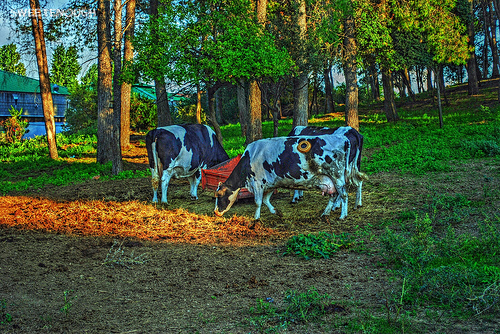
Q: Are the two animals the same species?
A: Yes, all the animals are cows.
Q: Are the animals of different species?
A: No, all the animals are cows.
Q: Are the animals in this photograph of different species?
A: No, all the animals are cows.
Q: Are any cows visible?
A: Yes, there is a cow.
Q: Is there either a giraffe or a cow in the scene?
A: Yes, there is a cow.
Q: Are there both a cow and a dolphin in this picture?
A: No, there is a cow but no dolphins.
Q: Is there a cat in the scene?
A: No, there are no cats.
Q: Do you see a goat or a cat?
A: No, there are no cats or goats.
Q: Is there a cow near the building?
A: Yes, there is a cow near the building.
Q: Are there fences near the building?
A: No, there is a cow near the building.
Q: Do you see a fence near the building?
A: No, there is a cow near the building.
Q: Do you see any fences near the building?
A: No, there is a cow near the building.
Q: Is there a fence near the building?
A: No, there is a cow near the building.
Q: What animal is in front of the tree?
A: The cow is in front of the tree.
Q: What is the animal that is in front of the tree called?
A: The animal is a cow.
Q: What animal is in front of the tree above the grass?
A: The animal is a cow.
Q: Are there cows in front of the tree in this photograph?
A: Yes, there is a cow in front of the tree.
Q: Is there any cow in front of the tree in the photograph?
A: Yes, there is a cow in front of the tree.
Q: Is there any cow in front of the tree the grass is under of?
A: Yes, there is a cow in front of the tree.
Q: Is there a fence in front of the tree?
A: No, there is a cow in front of the tree.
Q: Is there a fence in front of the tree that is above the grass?
A: No, there is a cow in front of the tree.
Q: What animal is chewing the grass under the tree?
A: The cow is chewing the grass.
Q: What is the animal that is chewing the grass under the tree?
A: The animal is a cow.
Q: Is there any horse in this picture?
A: No, there are no horses.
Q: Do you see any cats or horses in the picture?
A: No, there are no horses or cats.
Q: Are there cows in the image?
A: Yes, there is a cow.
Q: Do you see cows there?
A: Yes, there is a cow.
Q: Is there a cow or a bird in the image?
A: Yes, there is a cow.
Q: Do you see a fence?
A: No, there are no fences.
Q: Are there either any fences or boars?
A: No, there are no fences or boars.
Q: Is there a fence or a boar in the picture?
A: No, there are no fences or boars.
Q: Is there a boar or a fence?
A: No, there are no fences or boars.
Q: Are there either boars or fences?
A: No, there are no fences or boars.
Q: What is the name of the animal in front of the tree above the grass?
A: The animal is a cow.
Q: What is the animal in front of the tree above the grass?
A: The animal is a cow.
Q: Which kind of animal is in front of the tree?
A: The animal is a cow.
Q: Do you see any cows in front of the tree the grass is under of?
A: Yes, there is a cow in front of the tree.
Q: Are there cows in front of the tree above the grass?
A: Yes, there is a cow in front of the tree.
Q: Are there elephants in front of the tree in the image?
A: No, there is a cow in front of the tree.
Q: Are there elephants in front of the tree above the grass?
A: No, there is a cow in front of the tree.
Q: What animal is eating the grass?
A: The cow is eating the grass.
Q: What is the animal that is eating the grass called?
A: The animal is a cow.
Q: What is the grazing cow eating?
A: The cow is eating grass.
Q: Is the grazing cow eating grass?
A: Yes, the cow is eating grass.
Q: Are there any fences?
A: No, there are no fences.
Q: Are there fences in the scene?
A: No, there are no fences.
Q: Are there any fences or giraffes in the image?
A: No, there are no fences or giraffes.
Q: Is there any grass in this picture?
A: Yes, there is grass.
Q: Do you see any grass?
A: Yes, there is grass.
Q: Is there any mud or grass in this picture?
A: Yes, there is grass.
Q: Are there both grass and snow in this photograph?
A: No, there is grass but no snow.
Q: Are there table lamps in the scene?
A: No, there are no table lamps.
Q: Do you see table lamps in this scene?
A: No, there are no table lamps.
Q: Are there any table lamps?
A: No, there are no table lamps.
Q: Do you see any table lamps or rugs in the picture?
A: No, there are no table lamps or rugs.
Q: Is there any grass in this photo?
A: Yes, there is grass.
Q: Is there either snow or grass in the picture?
A: Yes, there is grass.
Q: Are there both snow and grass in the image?
A: No, there is grass but no snow.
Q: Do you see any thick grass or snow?
A: Yes, there is thick grass.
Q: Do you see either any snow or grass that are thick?
A: Yes, the grass is thick.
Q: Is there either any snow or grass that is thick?
A: Yes, the grass is thick.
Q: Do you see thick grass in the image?
A: Yes, there is thick grass.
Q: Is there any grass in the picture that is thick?
A: Yes, there is grass that is thick.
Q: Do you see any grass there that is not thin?
A: Yes, there is thick grass.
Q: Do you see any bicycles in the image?
A: No, there are no bicycles.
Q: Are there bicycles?
A: No, there are no bicycles.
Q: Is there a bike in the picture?
A: No, there are no bikes.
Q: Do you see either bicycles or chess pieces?
A: No, there are no bicycles or chess pieces.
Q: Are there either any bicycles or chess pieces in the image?
A: No, there are no bicycles or chess pieces.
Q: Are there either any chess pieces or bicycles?
A: No, there are no bicycles or chess pieces.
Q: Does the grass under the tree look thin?
A: No, the grass is thick.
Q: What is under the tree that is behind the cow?
A: The grass is under the tree.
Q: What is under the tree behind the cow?
A: The grass is under the tree.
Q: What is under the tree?
A: The grass is under the tree.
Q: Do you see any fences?
A: No, there are no fences.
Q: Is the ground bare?
A: Yes, the ground is bare.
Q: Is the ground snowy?
A: No, the ground is bare.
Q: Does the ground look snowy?
A: No, the ground is bare.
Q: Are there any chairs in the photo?
A: No, there are no chairs.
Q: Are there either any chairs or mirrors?
A: No, there are no chairs or mirrors.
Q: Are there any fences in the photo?
A: No, there are no fences.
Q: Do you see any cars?
A: No, there are no cars.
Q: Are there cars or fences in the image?
A: No, there are no cars or fences.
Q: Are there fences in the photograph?
A: No, there are no fences.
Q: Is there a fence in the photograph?
A: No, there are no fences.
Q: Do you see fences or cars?
A: No, there are no fences or cars.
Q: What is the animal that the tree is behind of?
A: The animal is a cow.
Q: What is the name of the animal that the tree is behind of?
A: The animal is a cow.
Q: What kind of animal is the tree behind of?
A: The tree is behind the cow.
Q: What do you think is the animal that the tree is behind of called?
A: The animal is a cow.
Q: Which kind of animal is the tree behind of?
A: The tree is behind the cow.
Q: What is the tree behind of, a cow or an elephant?
A: The tree is behind a cow.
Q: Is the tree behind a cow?
A: Yes, the tree is behind a cow.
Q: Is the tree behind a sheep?
A: No, the tree is behind a cow.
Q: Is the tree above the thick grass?
A: Yes, the tree is above the grass.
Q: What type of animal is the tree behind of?
A: The tree is behind the cow.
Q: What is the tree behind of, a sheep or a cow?
A: The tree is behind a cow.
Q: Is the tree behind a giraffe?
A: No, the tree is behind a cow.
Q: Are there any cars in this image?
A: No, there are no cars.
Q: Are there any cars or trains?
A: No, there are no cars or trains.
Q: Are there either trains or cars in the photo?
A: No, there are no cars or trains.